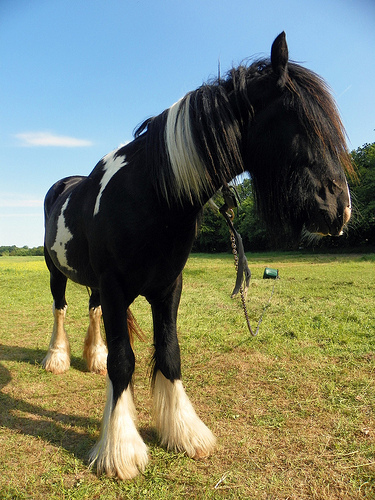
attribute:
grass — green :
[1, 255, 373, 497]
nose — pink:
[325, 191, 366, 218]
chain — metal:
[215, 176, 279, 338]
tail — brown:
[123, 307, 143, 347]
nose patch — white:
[342, 176, 352, 225]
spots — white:
[55, 203, 74, 272]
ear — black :
[249, 38, 312, 97]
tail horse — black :
[40, 33, 363, 480]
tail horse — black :
[33, 170, 150, 374]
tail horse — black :
[85, 29, 355, 484]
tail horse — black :
[42, 30, 375, 348]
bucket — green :
[261, 267, 279, 279]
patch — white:
[46, 196, 80, 273]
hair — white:
[163, 100, 211, 201]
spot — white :
[45, 197, 79, 264]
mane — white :
[134, 61, 258, 203]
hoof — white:
[46, 308, 70, 374]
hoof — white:
[83, 305, 113, 371]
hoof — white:
[95, 382, 151, 478]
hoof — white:
[145, 370, 218, 458]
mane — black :
[176, 75, 255, 180]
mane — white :
[162, 91, 216, 206]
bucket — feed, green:
[254, 261, 292, 300]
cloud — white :
[11, 120, 112, 152]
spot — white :
[90, 147, 127, 215]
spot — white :
[51, 193, 76, 272]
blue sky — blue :
[102, 15, 180, 58]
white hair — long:
[47, 348, 70, 366]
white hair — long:
[85, 345, 105, 366]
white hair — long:
[96, 433, 145, 462]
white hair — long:
[156, 401, 211, 447]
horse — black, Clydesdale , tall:
[42, 26, 347, 478]